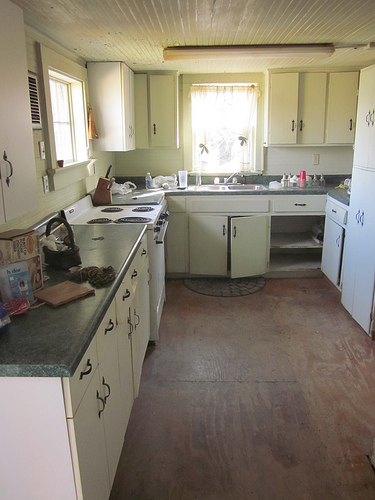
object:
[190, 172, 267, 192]
sink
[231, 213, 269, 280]
open cabinet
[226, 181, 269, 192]
sink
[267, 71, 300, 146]
cupboard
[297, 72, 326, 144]
cupboard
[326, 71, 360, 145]
cupboard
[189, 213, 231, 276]
cupboard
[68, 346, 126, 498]
cabinet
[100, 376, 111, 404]
handle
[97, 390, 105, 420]
handle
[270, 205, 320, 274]
cabinet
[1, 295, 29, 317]
can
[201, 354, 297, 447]
wood floor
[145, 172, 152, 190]
bottle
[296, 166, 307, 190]
can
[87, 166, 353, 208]
counter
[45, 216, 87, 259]
brown basket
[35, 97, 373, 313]
wall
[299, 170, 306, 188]
can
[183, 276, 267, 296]
mat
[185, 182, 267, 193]
sink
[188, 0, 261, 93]
window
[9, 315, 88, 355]
counter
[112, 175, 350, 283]
counter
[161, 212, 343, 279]
cabinet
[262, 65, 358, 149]
cabinet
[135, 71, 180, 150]
cabinet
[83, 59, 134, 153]
cabinet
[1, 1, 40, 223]
cabinet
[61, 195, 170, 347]
stove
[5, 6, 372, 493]
kitchen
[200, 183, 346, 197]
counter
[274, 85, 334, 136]
cabinet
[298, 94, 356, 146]
white surface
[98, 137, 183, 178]
wall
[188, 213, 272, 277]
cabinet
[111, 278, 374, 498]
floor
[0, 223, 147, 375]
counter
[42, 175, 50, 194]
electrical outlet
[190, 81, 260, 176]
curtains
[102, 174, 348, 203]
counter top